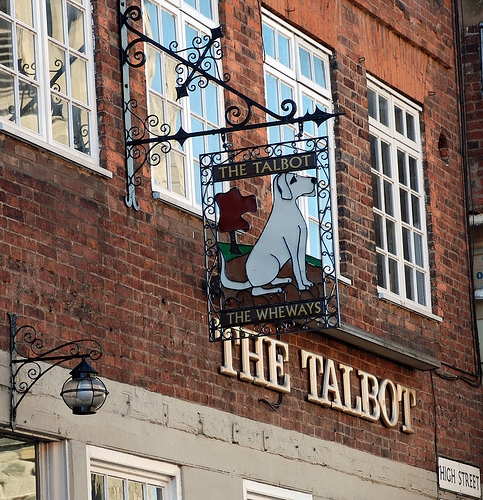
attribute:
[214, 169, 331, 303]
dog — white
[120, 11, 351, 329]
sign — iron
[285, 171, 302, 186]
eye — black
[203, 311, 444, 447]
lettering — white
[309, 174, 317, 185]
dog nose — black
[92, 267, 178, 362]
wall — red, brick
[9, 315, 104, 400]
hanger — iron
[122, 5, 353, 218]
sign hanger — decorative, iron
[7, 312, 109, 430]
lamp — black, metal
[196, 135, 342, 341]
sign — multi-colored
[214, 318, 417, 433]
lettering — gold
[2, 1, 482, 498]
building — brick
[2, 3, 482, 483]
brick wall — red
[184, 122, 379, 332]
sign — gold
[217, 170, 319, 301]
dog — white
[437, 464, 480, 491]
letters — black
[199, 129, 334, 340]
sign — fancy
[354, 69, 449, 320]
window — white